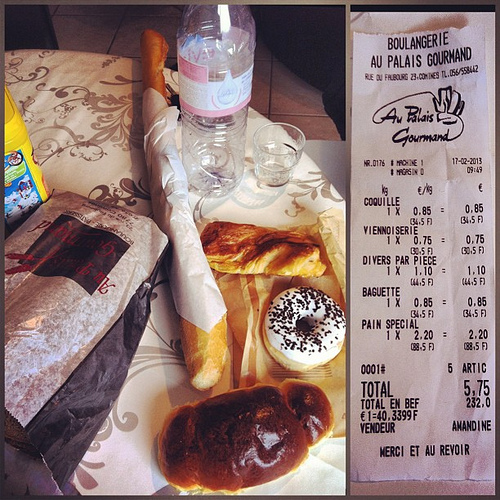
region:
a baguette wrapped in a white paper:
[139, 26, 228, 390]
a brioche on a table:
[157, 372, 334, 492]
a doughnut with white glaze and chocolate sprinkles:
[261, 290, 346, 367]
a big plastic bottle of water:
[176, 6, 257, 193]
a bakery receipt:
[353, 27, 498, 480]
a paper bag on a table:
[0, 189, 169, 417]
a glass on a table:
[249, 120, 304, 184]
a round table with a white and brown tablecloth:
[4, 45, 342, 495]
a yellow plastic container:
[6, 88, 51, 241]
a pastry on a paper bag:
[200, 222, 326, 275]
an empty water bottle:
[177, 3, 249, 195]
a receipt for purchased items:
[349, 27, 497, 484]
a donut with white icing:
[264, 285, 346, 370]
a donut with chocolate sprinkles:
[267, 288, 345, 370]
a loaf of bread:
[115, 27, 231, 388]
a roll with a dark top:
[156, 375, 333, 490]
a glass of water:
[253, 120, 305, 188]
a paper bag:
[3, 188, 165, 430]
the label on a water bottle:
[176, 55, 258, 116]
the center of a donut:
[290, 310, 322, 340]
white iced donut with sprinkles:
[254, 277, 348, 371]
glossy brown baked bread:
[134, 380, 336, 498]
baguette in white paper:
[131, 23, 231, 383]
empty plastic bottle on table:
[170, 10, 258, 215]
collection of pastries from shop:
[92, 18, 344, 498]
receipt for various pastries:
[341, 15, 495, 483]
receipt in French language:
[348, 18, 496, 480]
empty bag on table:
[2, 194, 170, 498]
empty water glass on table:
[250, 121, 305, 183]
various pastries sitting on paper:
[148, 214, 345, 492]